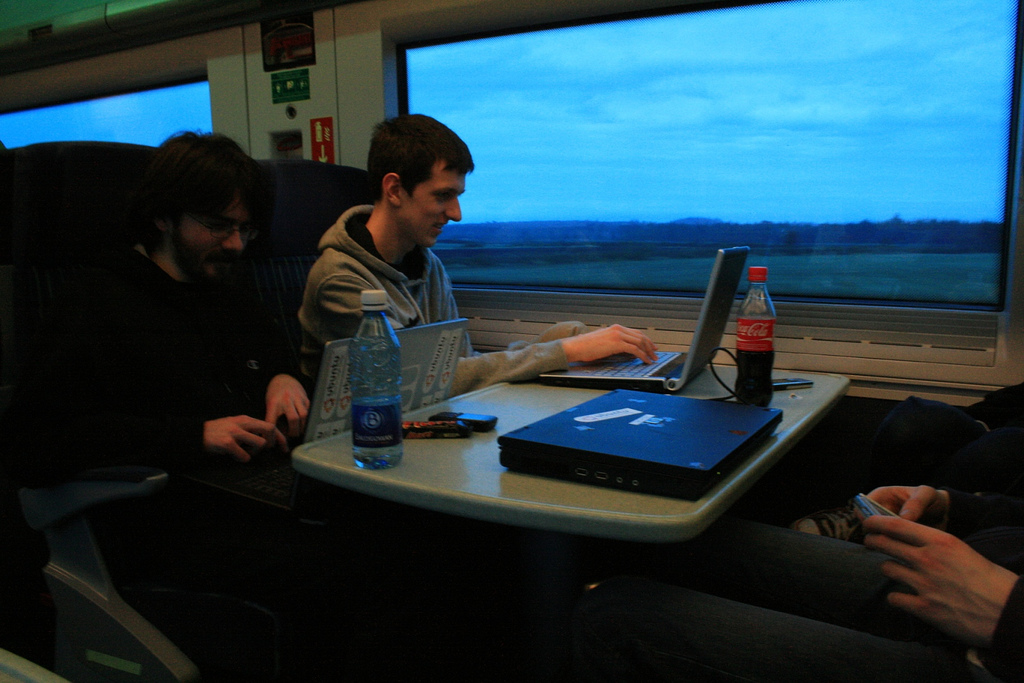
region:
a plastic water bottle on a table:
[339, 282, 401, 475]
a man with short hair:
[359, 100, 476, 189]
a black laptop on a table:
[495, 381, 770, 479]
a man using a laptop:
[136, 310, 465, 484]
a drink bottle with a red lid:
[727, 258, 779, 396]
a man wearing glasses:
[179, 206, 281, 244]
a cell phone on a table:
[422, 403, 506, 432]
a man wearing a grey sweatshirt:
[330, 213, 502, 334]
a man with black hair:
[133, 123, 271, 222]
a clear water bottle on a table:
[352, 285, 407, 466]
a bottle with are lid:
[733, 256, 779, 405]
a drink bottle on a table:
[737, 260, 780, 409]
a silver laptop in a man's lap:
[190, 305, 460, 473]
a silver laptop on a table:
[532, 235, 748, 390]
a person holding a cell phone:
[847, 462, 936, 570]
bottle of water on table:
[343, 279, 410, 467]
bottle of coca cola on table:
[734, 263, 783, 407]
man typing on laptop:
[78, 131, 487, 669]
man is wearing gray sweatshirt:
[305, 114, 582, 424]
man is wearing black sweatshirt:
[62, 134, 386, 676]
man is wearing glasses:
[137, 133, 277, 318]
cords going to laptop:
[502, 344, 788, 529]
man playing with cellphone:
[597, 468, 1021, 677]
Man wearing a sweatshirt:
[291, 191, 609, 414]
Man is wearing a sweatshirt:
[289, 194, 588, 406]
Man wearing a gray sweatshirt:
[289, 193, 593, 406]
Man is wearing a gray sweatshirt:
[299, 188, 601, 395]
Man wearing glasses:
[177, 187, 266, 255]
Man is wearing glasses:
[174, 179, 267, 253]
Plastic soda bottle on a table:
[721, 253, 799, 409]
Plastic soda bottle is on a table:
[710, 245, 791, 433]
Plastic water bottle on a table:
[332, 275, 418, 473]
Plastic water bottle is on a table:
[337, 277, 411, 484]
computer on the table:
[551, 411, 695, 479]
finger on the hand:
[879, 522, 930, 543]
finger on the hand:
[874, 540, 922, 566]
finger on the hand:
[871, 559, 917, 580]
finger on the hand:
[879, 578, 930, 613]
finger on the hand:
[890, 500, 935, 523]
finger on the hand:
[861, 478, 894, 510]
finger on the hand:
[231, 443, 261, 451]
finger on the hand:
[263, 389, 277, 418]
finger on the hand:
[598, 331, 655, 371]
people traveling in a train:
[19, 23, 1015, 660]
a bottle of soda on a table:
[719, 253, 798, 416]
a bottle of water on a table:
[341, 278, 415, 476]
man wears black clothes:
[66, 109, 333, 608]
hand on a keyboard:
[530, 300, 686, 397]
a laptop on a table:
[480, 374, 792, 504]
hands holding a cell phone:
[827, 466, 1022, 622]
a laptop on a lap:
[150, 273, 479, 473]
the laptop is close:
[466, 364, 795, 508]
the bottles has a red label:
[727, 259, 793, 409]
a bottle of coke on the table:
[721, 261, 799, 411]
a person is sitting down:
[303, 109, 648, 397]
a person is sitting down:
[44, 119, 475, 677]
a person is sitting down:
[598, 367, 1016, 680]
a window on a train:
[401, 7, 993, 358]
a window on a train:
[7, 83, 213, 156]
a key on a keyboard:
[652, 345, 665, 356]